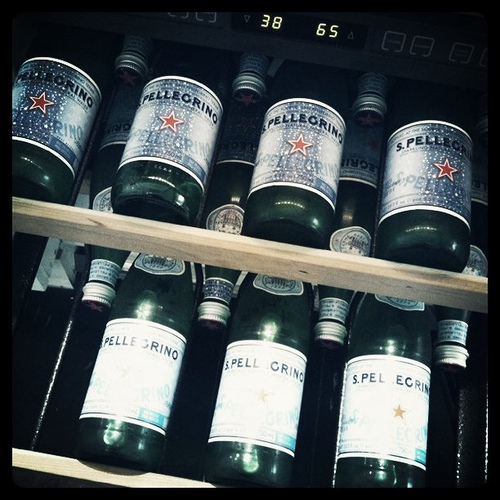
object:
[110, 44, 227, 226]
beer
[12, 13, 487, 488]
cooler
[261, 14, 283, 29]
number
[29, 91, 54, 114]
star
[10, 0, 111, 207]
bottle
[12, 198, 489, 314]
shelf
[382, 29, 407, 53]
button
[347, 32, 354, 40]
arrow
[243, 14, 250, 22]
arrow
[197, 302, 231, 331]
lid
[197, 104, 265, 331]
bottle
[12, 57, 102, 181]
label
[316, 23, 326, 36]
six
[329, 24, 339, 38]
five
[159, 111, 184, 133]
star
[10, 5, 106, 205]
wine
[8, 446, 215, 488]
rack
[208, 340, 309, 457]
label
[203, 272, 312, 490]
bottle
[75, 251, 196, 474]
water